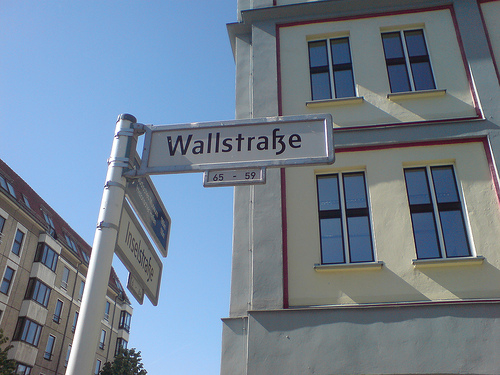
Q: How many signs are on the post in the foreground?
A: Three.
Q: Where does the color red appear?
A: Around the sets of two windows.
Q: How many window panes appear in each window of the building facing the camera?
A: Four.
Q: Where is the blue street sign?
A: At the top of the metal pole perpendicular to the camera.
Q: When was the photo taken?
A: During the day.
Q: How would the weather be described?
A: Sunny and clear.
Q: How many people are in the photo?
A: None.